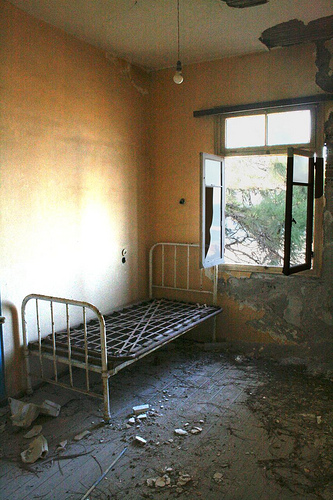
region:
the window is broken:
[195, 155, 228, 270]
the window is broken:
[184, 135, 244, 288]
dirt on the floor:
[96, 402, 205, 483]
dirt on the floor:
[126, 413, 186, 475]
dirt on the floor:
[143, 412, 226, 492]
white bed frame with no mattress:
[18, 239, 223, 420]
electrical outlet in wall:
[119, 245, 130, 264]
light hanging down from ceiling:
[168, 2, 187, 86]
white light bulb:
[170, 67, 187, 87]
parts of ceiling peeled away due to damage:
[216, 2, 331, 54]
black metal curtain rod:
[180, 90, 331, 119]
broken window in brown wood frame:
[193, 150, 229, 270]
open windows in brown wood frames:
[194, 143, 313, 277]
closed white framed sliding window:
[204, 98, 322, 156]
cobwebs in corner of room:
[101, 45, 157, 101]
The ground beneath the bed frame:
[0, 334, 331, 499]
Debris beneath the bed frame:
[0, 342, 331, 497]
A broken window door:
[283, 151, 311, 274]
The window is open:
[221, 154, 312, 269]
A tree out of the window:
[224, 157, 309, 265]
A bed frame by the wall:
[22, 243, 216, 419]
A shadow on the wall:
[2, 300, 21, 388]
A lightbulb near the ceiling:
[174, 4, 182, 84]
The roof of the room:
[10, 0, 332, 69]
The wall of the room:
[2, 2, 331, 356]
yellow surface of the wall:
[57, 113, 132, 213]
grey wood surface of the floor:
[50, 459, 91, 492]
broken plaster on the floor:
[118, 404, 210, 498]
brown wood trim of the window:
[281, 137, 320, 278]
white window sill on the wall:
[225, 261, 276, 278]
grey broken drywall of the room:
[237, 279, 332, 347]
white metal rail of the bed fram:
[79, 316, 108, 414]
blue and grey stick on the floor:
[76, 443, 128, 493]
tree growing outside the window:
[237, 184, 283, 265]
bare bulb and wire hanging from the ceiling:
[158, 0, 195, 92]